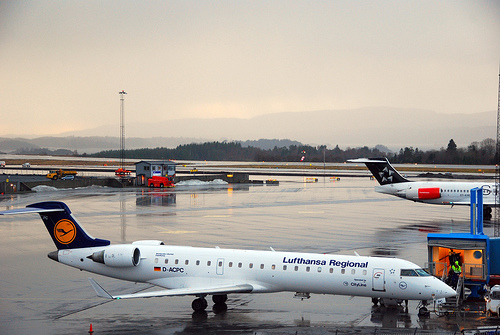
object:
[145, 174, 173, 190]
car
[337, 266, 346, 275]
window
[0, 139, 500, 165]
tree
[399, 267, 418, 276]
window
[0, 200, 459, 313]
plane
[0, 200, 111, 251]
tail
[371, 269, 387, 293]
door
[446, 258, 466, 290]
man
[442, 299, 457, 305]
steps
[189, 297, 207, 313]
tires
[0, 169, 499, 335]
airport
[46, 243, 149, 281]
cone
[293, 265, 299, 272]
small window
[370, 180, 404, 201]
jet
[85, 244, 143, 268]
engine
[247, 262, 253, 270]
window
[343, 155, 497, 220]
plane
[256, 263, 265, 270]
window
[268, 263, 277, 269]
window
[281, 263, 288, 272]
window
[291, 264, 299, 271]
window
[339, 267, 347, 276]
window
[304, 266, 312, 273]
window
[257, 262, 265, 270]
window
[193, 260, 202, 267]
window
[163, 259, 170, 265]
window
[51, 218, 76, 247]
logo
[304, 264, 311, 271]
window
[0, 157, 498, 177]
pavement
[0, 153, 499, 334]
ground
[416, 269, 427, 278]
windshield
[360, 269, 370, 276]
window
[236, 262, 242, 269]
window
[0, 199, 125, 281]
terminal